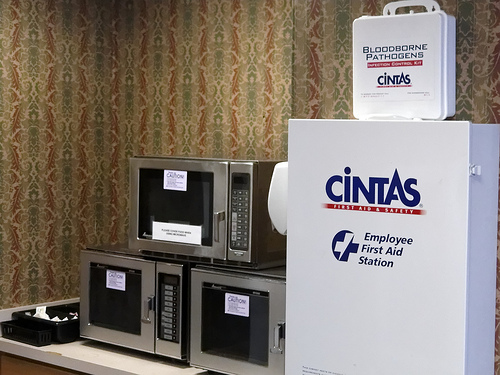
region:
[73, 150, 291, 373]
three microwaves on counter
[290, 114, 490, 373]
First aid kit on counter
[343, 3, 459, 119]
blood borne pathogen kit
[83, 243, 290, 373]
two microwaves on counter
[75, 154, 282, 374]
black and silver microwaves on counter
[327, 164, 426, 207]
blue writing on first aid kit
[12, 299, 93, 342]
condiment tray on counter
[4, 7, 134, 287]
patterned wall paper on walls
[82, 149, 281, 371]
microwaves in front of wall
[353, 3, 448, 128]
small kit on top of large first aid station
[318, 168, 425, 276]
A logo on the first aid kit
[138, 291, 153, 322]
A handle on the microwave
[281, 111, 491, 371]
A first aid kit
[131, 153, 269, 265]
A microwave on top of another microwave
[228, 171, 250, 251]
Buttons on the microwave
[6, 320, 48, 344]
An empty basket next to the microwave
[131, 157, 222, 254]
The door on the microwave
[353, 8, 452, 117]
A case for bloodborne pathogens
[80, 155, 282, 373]
Microwaves on the counter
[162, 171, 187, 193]
A caution label on the microwave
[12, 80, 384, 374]
three microwaves on a table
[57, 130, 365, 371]
a microwave stacked on top of two microwaves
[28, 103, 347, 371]
a microwave on top of two other microwaves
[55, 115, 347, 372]
three silver microwave on a table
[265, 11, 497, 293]
cintas first aid container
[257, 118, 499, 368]
employee first aid station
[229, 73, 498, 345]
cintas first aid station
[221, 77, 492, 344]
cintas employee first aid station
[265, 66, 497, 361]
cintas employee first aid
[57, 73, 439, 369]
microwaves next to first aid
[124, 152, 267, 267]
Stainless steel microwave.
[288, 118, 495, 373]
First Aid box.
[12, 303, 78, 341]
Condiments in a black tray.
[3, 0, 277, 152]
Tan wallpaper with green and red designs.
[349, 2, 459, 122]
Cintas bloodborne pathogens kit.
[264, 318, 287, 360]
Handle on microwave door.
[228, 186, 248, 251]
Number pad on microwave.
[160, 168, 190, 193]
Sticker on front of microwave.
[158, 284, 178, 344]
Food selector on microwave.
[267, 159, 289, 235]
Hand sanitize dispenser.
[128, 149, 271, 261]
a black and grey microwave ovan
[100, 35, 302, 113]
a multi-coloured curtains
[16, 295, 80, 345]
black colour tray kept in the table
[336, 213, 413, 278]
some blue colour letter written in the box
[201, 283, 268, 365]
a black colour glass in front of the ovan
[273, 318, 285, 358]
a handle of the microwave ovan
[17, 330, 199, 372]
a white colour top of the table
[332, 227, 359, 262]
plus symbol in the box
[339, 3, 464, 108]
some white colour box hanging in the wall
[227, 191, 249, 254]
control switches of the ovan